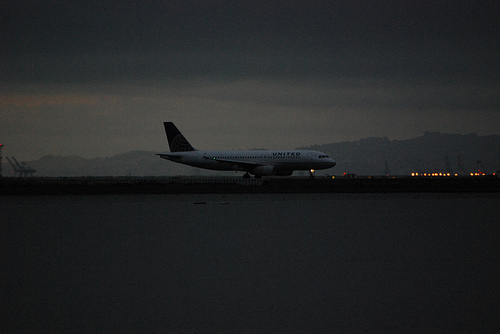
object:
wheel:
[309, 175, 315, 181]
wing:
[216, 158, 270, 166]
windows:
[213, 155, 301, 159]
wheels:
[242, 174, 251, 180]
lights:
[411, 172, 486, 177]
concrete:
[0, 195, 499, 333]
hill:
[0, 130, 500, 176]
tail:
[163, 121, 196, 152]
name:
[272, 152, 301, 157]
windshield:
[318, 155, 330, 158]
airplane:
[154, 121, 337, 179]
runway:
[0, 195, 500, 334]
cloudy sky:
[0, 0, 499, 152]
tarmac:
[0, 177, 499, 195]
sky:
[1, 0, 499, 154]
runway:
[0, 171, 499, 196]